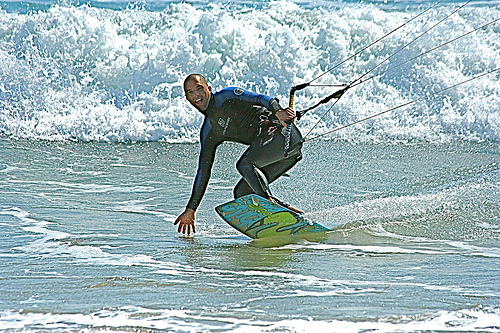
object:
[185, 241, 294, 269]
shadow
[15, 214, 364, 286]
waves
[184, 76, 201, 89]
forehead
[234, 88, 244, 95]
logo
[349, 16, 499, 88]
cords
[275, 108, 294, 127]
hand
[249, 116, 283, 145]
reins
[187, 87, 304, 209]
body suit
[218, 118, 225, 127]
logo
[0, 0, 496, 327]
water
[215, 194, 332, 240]
surfboard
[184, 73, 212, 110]
head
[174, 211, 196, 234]
hand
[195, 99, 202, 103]
mouth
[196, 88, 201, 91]
eye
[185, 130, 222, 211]
arm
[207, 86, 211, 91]
ear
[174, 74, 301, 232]
man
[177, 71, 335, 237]
surfing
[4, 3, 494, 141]
wave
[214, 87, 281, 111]
fabric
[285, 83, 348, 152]
contraption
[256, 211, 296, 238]
s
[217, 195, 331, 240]
bottom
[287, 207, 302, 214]
feet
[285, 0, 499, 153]
parasail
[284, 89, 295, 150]
handle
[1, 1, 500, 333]
air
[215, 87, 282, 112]
right arm